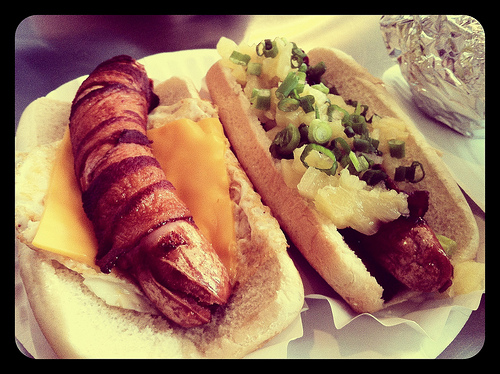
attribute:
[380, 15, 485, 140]
foil — tin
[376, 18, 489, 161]
paper — aluminum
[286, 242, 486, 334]
doily — paper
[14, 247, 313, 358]
doily — paper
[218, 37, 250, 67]
onion — green, thin, long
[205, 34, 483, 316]
hot dog — red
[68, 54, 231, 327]
sausage — red , long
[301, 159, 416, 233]
onions — white, chopped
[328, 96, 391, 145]
slice — green, thin, long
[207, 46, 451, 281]
hot dog — red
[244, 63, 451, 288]
hotdog — red, long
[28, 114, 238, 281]
cheese — melted, yellow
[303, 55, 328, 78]
onion — green, thin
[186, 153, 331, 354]
bun — brown